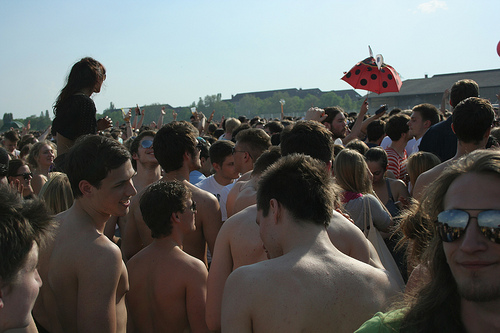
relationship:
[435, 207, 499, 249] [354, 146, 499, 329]
sunglasses on man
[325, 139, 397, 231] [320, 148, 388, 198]
woman's has bag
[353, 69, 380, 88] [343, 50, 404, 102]
polka dots on umbrella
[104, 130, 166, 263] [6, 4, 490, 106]
man looking up to sky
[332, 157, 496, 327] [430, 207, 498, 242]
man wearing sunglasses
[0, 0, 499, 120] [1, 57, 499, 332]
sky above people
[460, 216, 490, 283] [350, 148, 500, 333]
nose of man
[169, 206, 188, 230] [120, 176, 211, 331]
ear of man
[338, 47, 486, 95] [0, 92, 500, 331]
umbrella in crowd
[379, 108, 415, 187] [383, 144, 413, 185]
person wearing shirt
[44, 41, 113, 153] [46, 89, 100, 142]
person wearing shirt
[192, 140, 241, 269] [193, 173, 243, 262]
man wearing shirt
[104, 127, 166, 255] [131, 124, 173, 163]
man wearing sun glasses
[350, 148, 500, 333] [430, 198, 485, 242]
man wearing sunglasses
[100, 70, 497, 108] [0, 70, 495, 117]
buildings in background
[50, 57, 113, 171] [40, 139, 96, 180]
person sitting on shoulders